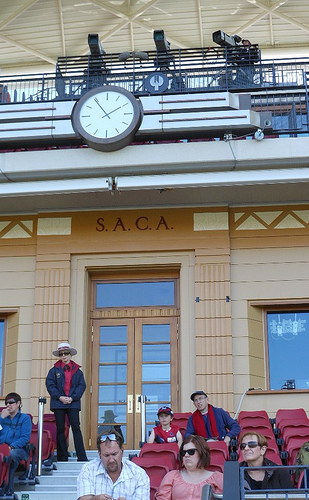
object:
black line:
[105, 89, 109, 102]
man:
[78, 418, 154, 500]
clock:
[70, 81, 144, 154]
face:
[78, 89, 134, 140]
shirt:
[156, 467, 223, 500]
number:
[114, 93, 122, 102]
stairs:
[51, 458, 88, 470]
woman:
[44, 340, 89, 464]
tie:
[62, 364, 72, 373]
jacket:
[44, 356, 86, 411]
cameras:
[153, 27, 172, 54]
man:
[183, 389, 242, 450]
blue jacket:
[183, 402, 240, 447]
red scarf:
[191, 402, 220, 443]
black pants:
[53, 409, 88, 462]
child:
[146, 404, 183, 450]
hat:
[155, 404, 174, 417]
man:
[44, 340, 89, 463]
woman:
[153, 429, 226, 498]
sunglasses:
[57, 349, 70, 357]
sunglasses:
[178, 446, 199, 457]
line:
[84, 103, 92, 109]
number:
[80, 112, 92, 119]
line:
[105, 128, 108, 139]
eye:
[111, 450, 117, 457]